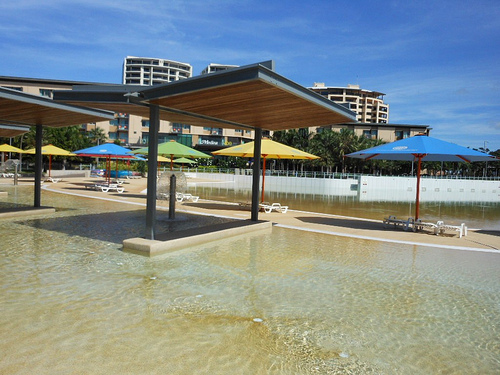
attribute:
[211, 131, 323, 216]
umbrella — yellow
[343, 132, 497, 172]
umbrella — blue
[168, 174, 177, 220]
pole — small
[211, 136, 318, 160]
umbrella — yellow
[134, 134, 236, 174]
umbrella — green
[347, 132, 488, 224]
umbrella — blue